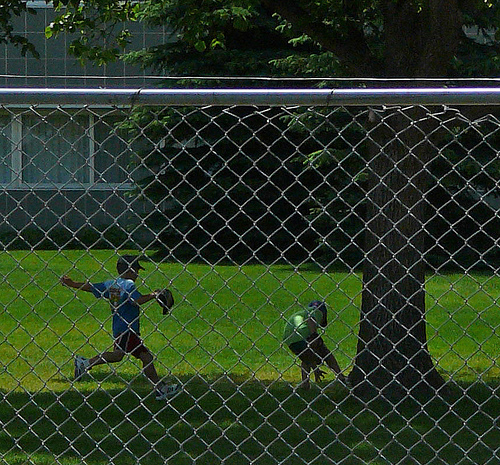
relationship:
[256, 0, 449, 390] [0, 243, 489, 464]
tree growing in yard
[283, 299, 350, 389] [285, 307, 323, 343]
boy wearing shirt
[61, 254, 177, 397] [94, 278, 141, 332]
boy wearing shirt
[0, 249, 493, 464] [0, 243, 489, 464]
grass growing in yard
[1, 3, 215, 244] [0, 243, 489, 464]
house next to yard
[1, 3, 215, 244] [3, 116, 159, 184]
house has window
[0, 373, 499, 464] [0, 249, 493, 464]
shadow cast on grass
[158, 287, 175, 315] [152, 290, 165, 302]
glove on hand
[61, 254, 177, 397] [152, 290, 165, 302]
boy has hand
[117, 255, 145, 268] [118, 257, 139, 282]
cap on head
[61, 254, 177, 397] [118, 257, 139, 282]
boy has head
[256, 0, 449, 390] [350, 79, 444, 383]
tree has trunk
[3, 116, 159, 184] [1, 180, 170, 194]
window has frame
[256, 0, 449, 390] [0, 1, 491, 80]
tree has leaves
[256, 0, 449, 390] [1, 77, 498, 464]
tree growing behind fence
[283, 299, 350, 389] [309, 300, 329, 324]
boy wearing hat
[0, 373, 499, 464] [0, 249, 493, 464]
shadow on grass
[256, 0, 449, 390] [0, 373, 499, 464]
tree casts shadow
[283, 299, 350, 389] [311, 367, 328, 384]
boy has hand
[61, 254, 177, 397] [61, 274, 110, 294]
boy has arm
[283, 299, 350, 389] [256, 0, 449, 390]
boy next to tree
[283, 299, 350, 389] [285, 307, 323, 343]
boy has shirt